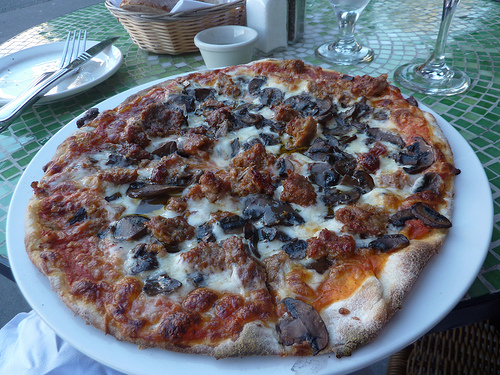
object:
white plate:
[5, 80, 494, 374]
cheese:
[73, 271, 106, 308]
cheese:
[69, 130, 112, 141]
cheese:
[280, 67, 320, 84]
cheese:
[361, 71, 393, 106]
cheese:
[165, 302, 202, 349]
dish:
[6, 67, 491, 373]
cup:
[192, 23, 258, 70]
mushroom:
[276, 297, 328, 354]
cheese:
[193, 197, 221, 221]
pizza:
[25, 57, 459, 360]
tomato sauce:
[93, 81, 375, 240]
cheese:
[34, 56, 459, 362]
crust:
[333, 260, 381, 327]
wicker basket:
[99, 1, 266, 61]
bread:
[119, 3, 184, 16]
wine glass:
[391, 0, 484, 98]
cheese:
[213, 269, 240, 291]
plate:
[445, 137, 497, 288]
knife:
[0, 34, 119, 125]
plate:
[2, 40, 121, 105]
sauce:
[160, 195, 309, 288]